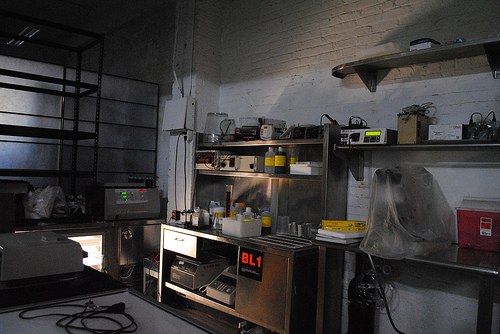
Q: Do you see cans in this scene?
A: No, there are no cans.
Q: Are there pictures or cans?
A: No, there are no cans or pictures.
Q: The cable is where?
A: The cable is on the floor.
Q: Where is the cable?
A: The cable is on the floor.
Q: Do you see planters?
A: No, there are no planters.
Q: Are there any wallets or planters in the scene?
A: No, there are no planters or wallets.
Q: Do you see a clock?
A: No, there are no clocks.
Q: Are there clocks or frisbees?
A: No, there are no clocks or frisbees.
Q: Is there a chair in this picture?
A: No, there are no chairs.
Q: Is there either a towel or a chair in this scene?
A: No, there are no chairs or towels.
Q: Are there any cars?
A: No, there are no cars.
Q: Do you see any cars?
A: No, there are no cars.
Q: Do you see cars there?
A: No, there are no cars.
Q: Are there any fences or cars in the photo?
A: No, there are no cars or fences.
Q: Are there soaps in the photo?
A: No, there are no soaps.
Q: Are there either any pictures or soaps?
A: No, there are no soaps or pictures.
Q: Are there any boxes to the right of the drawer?
A: Yes, there is a box to the right of the drawer.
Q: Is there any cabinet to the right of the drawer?
A: No, there is a box to the right of the drawer.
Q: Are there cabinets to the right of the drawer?
A: No, there is a box to the right of the drawer.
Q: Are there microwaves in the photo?
A: No, there are no microwaves.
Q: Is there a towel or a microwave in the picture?
A: No, there are no microwaves or towels.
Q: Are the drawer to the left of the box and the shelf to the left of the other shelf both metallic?
A: Yes, both the drawer and the shelf are metallic.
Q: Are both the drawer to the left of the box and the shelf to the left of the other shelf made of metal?
A: Yes, both the drawer and the shelf are made of metal.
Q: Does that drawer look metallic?
A: Yes, the drawer is metallic.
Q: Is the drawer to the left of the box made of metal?
A: Yes, the drawer is made of metal.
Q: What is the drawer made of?
A: The drawer is made of metal.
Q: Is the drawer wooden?
A: No, the drawer is metallic.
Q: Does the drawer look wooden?
A: No, the drawer is metallic.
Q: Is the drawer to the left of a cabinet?
A: No, the drawer is to the left of the box.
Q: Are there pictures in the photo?
A: No, there are no pictures.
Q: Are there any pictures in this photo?
A: No, there are no pictures.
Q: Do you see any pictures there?
A: No, there are no pictures.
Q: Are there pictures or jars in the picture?
A: No, there are no pictures or jars.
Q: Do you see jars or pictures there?
A: No, there are no pictures or jars.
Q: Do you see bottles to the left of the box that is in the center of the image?
A: Yes, there are bottles to the left of the box.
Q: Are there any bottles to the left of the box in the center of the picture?
A: Yes, there are bottles to the left of the box.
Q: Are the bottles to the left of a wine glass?
A: No, the bottles are to the left of the box.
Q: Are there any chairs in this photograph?
A: No, there are no chairs.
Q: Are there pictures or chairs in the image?
A: No, there are no chairs or pictures.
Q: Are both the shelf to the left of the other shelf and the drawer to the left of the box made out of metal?
A: Yes, both the shelf and the drawer are made of metal.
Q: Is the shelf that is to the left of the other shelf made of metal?
A: Yes, the shelf is made of metal.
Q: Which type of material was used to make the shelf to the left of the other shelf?
A: The shelf is made of metal.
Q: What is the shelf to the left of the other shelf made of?
A: The shelf is made of metal.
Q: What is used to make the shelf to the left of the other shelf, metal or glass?
A: The shelf is made of metal.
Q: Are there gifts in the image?
A: No, there are no gifts.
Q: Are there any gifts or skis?
A: No, there are no gifts or skis.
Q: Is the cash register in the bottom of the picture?
A: Yes, the cash register is in the bottom of the image.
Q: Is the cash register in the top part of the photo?
A: No, the cash register is in the bottom of the image.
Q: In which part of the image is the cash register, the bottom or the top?
A: The cash register is in the bottom of the image.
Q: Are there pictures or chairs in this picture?
A: No, there are no pictures or chairs.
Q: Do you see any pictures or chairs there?
A: No, there are no pictures or chairs.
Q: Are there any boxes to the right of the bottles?
A: Yes, there is a box to the right of the bottles.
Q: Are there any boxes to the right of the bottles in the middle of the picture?
A: Yes, there is a box to the right of the bottles.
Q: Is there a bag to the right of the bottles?
A: No, there is a box to the right of the bottles.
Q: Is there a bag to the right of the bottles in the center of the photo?
A: No, there is a box to the right of the bottles.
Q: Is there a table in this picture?
A: Yes, there is a table.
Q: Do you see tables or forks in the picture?
A: Yes, there is a table.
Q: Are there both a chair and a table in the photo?
A: No, there is a table but no chairs.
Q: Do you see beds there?
A: No, there are no beds.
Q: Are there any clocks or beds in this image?
A: No, there are no beds or clocks.